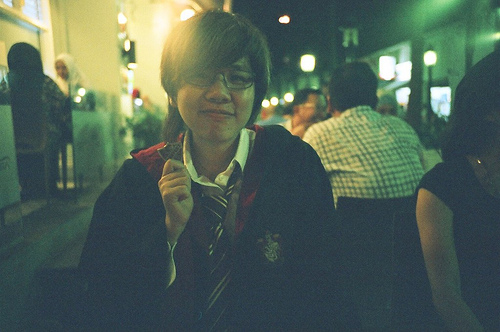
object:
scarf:
[49, 51, 81, 94]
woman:
[51, 52, 104, 191]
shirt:
[301, 105, 429, 209]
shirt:
[413, 150, 500, 332]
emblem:
[257, 231, 282, 263]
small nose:
[205, 72, 232, 104]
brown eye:
[187, 69, 208, 79]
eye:
[230, 73, 242, 82]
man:
[77, 10, 347, 332]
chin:
[192, 120, 237, 142]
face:
[295, 93, 328, 123]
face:
[54, 59, 68, 80]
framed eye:
[182, 64, 255, 90]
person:
[0, 41, 71, 202]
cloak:
[76, 123, 343, 332]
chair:
[20, 261, 84, 330]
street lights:
[276, 16, 291, 25]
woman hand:
[158, 159, 196, 223]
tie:
[193, 164, 241, 331]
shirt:
[181, 127, 255, 196]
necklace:
[465, 153, 498, 188]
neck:
[468, 139, 500, 164]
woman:
[413, 41, 499, 332]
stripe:
[209, 193, 229, 207]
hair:
[158, 7, 270, 145]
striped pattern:
[205, 268, 232, 328]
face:
[176, 54, 256, 141]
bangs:
[160, 43, 249, 102]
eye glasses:
[180, 64, 257, 89]